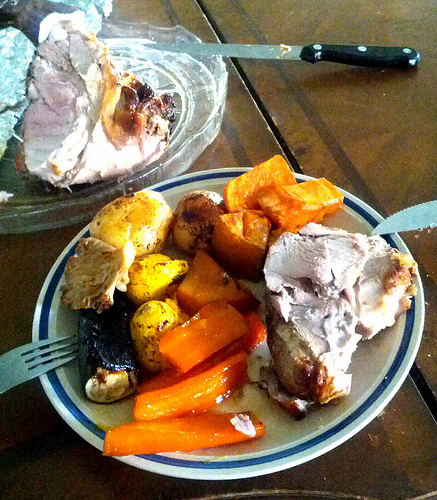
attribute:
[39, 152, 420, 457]
dish — white, blue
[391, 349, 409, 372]
border — blue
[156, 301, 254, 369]
carrot — sliced, orange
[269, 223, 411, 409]
meat — white, sliced, grilled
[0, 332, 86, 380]
fork — metal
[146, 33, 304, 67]
knife blade — silver, serrated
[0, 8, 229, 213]
container — plastic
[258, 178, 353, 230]
sweet potato — cooked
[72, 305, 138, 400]
zucchini — green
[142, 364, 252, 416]
carrot — sliced, orange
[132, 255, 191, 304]
dollop — yellow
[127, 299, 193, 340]
dollop — yellow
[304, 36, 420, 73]
knife handle — black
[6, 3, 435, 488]
table — wooden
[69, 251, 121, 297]
food — cooked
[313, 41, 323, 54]
circle — silver